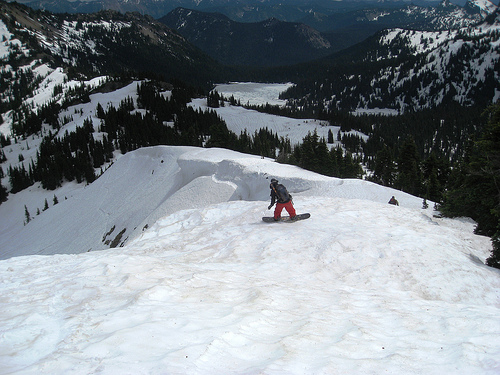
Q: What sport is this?
A: Snowboard.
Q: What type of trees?
A: Evergreen.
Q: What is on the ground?
A: Snow.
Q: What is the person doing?
A: Snowboarding.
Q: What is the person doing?
A: Snowboarding.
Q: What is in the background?
A: Mountain.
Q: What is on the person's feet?
A: Snowboard.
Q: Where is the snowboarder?
A: A mountain.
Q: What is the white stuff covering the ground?
A: Snow.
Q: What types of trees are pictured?
A: Evergreen.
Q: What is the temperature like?
A: Cold.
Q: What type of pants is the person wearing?
A: Ski pants.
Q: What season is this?
A: Winter.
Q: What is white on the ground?
A: Snow.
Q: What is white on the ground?
A: Snow.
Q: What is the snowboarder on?
A: White snow.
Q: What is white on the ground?
A: Snow.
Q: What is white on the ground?
A: Snow.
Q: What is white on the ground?
A: Snow.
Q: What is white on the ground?
A: Snow.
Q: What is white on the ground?
A: Snow.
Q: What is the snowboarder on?
A: A snowy white slope.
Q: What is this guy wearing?
A: Cold weather gear.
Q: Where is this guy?
A: On top a snowy mountain.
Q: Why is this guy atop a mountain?
A: He is snowboarding.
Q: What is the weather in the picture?
A: Freezing cold.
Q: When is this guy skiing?
A: Early in the morning.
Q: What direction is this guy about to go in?
A: The left.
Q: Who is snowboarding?
A: A guy.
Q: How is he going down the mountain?
A: Sliding.